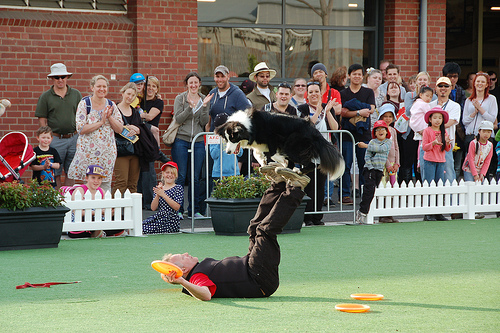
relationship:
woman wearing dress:
[74, 69, 124, 190] [82, 97, 113, 184]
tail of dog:
[316, 131, 343, 182] [213, 107, 345, 182]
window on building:
[199, 2, 374, 73] [1, 2, 491, 74]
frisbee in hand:
[151, 260, 184, 278] [154, 270, 188, 287]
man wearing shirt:
[35, 70, 120, 168] [29, 79, 117, 151]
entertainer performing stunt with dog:
[159, 164, 311, 301] [202, 102, 364, 195]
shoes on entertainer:
[253, 158, 330, 196] [159, 164, 311, 301]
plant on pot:
[210, 169, 275, 201] [201, 191, 312, 237]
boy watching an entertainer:
[24, 120, 72, 188] [145, 162, 314, 306]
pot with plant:
[202, 196, 307, 233] [211, 173, 267, 197]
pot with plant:
[3, 204, 68, 249] [1, 179, 66, 211]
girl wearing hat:
[144, 154, 189, 240] [157, 154, 181, 174]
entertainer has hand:
[159, 164, 311, 301] [153, 260, 190, 291]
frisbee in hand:
[137, 242, 194, 294] [153, 260, 190, 291]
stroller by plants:
[5, 126, 39, 187] [7, 175, 64, 209]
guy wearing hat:
[245, 60, 277, 107] [248, 60, 275, 80]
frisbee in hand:
[151, 260, 184, 278] [165, 271, 185, 284]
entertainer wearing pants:
[159, 164, 311, 301] [248, 177, 326, 264]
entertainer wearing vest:
[159, 164, 311, 301] [188, 255, 252, 295]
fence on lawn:
[374, 170, 496, 214] [348, 216, 499, 277]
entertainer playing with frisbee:
[159, 164, 311, 301] [149, 259, 183, 277]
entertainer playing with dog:
[159, 164, 311, 301] [213, 107, 345, 182]